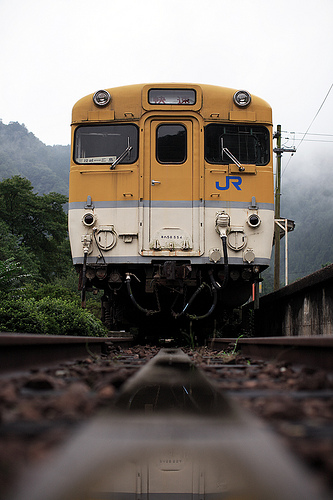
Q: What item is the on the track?
A: A train.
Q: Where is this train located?
A: In Asia.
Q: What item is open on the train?
A: The door.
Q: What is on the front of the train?
A: Wires and tubes.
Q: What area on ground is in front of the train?
A: The train tracks.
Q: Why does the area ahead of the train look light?
A: They are on the fog.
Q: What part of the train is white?
A: The bottom.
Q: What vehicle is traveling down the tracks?
A: A train.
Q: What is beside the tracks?
A: Trees and shrubbery.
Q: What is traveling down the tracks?
A: A train.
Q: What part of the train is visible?
A: The caboose.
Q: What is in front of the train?
A: The mountains.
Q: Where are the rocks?
A: On railroad tracks.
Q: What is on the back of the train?
A: Windows.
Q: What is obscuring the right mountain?
A: Fog.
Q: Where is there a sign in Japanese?
A: Above the door.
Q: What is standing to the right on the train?
A: Telephone pole.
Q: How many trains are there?
A: One.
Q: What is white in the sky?
A: Fog.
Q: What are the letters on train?
A: J R.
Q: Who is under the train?
A: No one.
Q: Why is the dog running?
A: No dog.